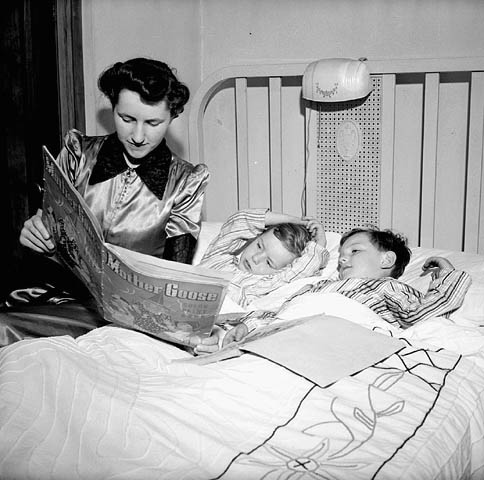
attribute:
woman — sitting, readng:
[18, 57, 211, 306]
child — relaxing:
[192, 205, 327, 311]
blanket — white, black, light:
[5, 303, 477, 479]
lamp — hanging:
[299, 59, 377, 109]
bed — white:
[188, 72, 483, 263]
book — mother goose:
[38, 146, 228, 344]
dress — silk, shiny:
[53, 132, 206, 265]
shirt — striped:
[211, 211, 321, 316]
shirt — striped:
[290, 276, 468, 319]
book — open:
[186, 316, 406, 387]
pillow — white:
[347, 232, 483, 327]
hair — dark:
[96, 63, 193, 110]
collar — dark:
[92, 132, 173, 196]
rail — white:
[231, 80, 255, 212]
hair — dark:
[341, 230, 411, 279]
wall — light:
[80, 3, 478, 247]